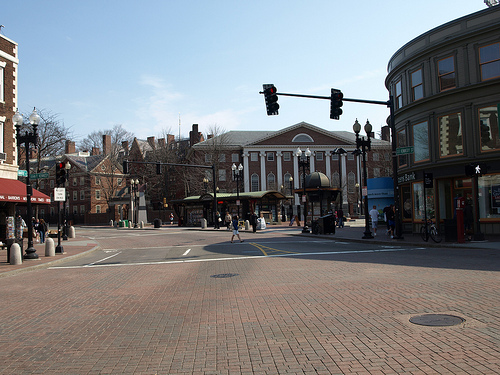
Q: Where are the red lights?
A: On the Street lamps.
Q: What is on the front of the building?
A: Pillars.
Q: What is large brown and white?
A: The building.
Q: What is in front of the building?
A: White columns.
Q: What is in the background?
A: A building.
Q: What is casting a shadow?
A: The building.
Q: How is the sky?
A: The sky is clear.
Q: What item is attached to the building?
A: The traffic light.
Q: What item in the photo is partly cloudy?
A: The sky.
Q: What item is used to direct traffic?
A: Traffic lights.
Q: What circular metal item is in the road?
A: A manhole.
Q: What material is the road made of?
A: Brick.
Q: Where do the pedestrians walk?
A: The crosswalk.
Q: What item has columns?
A: A building.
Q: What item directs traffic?
A: Traffic light.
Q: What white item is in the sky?
A: Clouds.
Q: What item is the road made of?
A: Bricks.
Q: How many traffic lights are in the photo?
A: Five.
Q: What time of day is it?
A: Daytime.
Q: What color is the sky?
A: Blue.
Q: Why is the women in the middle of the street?
A: Walking to the other side.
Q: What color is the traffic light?
A: Red.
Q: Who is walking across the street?
A: A woman.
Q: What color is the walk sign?
A: White.